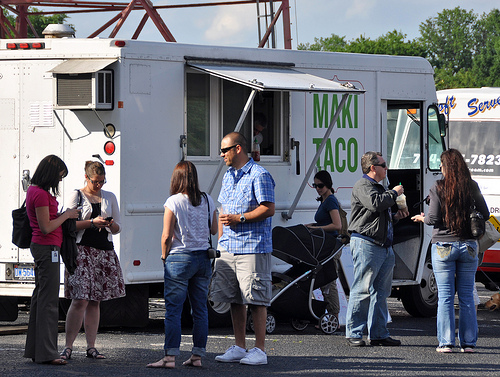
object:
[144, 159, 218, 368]
person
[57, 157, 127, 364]
person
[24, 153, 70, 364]
person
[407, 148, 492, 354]
person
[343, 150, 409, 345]
guy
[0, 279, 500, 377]
cement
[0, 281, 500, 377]
ground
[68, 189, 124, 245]
cardigan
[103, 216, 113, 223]
cell phone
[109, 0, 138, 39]
pole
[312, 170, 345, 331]
woman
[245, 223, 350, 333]
baby stroller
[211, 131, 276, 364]
guy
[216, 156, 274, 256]
shirt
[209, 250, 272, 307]
shorts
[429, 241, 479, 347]
jeans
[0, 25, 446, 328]
truck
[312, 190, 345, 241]
t-shirt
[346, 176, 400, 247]
jacket